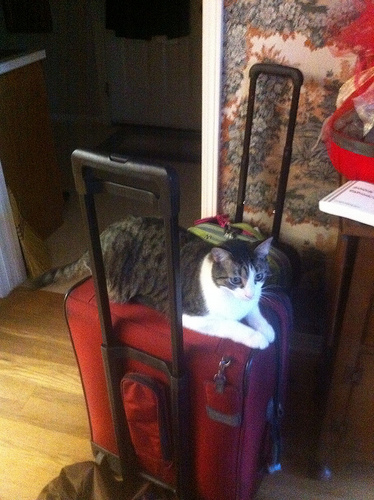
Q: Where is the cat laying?
A: On the suitcase.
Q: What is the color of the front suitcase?
A: Red.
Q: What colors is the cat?
A: Gray and white.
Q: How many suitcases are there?
A: Two.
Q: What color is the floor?
A: Brown.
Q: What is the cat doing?
A: Laying down.